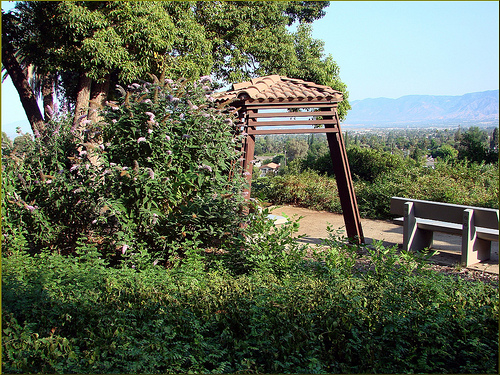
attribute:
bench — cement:
[383, 193, 479, 257]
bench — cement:
[374, 195, 483, 266]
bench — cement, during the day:
[379, 189, 483, 267]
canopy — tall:
[195, 67, 371, 251]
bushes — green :
[69, 224, 481, 342]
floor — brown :
[266, 205, 329, 242]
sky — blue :
[347, 4, 477, 126]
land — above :
[274, 202, 325, 232]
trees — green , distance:
[403, 122, 480, 170]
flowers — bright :
[78, 114, 94, 165]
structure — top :
[232, 98, 376, 243]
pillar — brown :
[330, 131, 372, 240]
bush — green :
[18, 241, 482, 353]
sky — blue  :
[333, 17, 474, 87]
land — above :
[263, 199, 421, 240]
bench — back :
[385, 197, 482, 259]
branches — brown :
[72, 39, 125, 81]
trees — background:
[12, 134, 265, 295]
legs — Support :
[230, 140, 377, 244]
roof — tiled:
[204, 73, 344, 107]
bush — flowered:
[1, 77, 305, 263]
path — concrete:
[268, 204, 498, 284]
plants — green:
[1, 205, 499, 374]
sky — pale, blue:
[311, 2, 499, 97]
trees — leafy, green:
[1, 1, 349, 166]